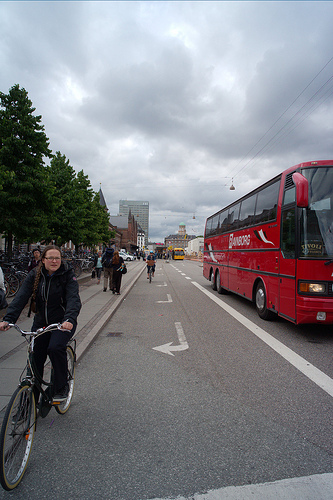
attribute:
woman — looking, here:
[15, 248, 105, 333]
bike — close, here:
[2, 357, 83, 476]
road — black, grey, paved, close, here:
[111, 273, 293, 459]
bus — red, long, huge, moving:
[214, 160, 326, 330]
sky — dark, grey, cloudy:
[91, 12, 296, 134]